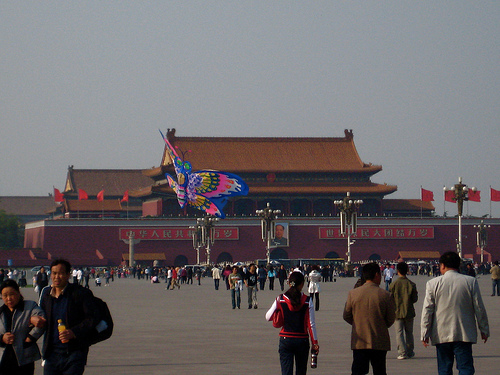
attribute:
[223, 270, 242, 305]
person — walking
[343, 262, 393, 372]
person — walking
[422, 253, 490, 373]
person — walking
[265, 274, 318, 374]
person — walking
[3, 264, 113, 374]
person — walking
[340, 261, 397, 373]
person — walking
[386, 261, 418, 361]
person — walking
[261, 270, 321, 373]
person — walking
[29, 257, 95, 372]
person — walking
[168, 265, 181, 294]
person — walking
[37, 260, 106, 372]
person — walking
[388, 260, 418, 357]
person — walking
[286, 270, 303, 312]
hair — long 